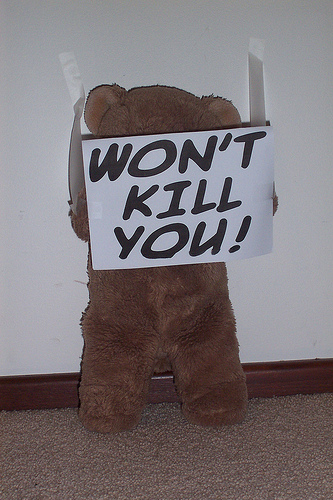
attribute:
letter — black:
[215, 176, 245, 214]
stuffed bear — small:
[68, 82, 249, 433]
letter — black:
[95, 143, 126, 172]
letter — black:
[124, 135, 179, 181]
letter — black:
[177, 134, 218, 176]